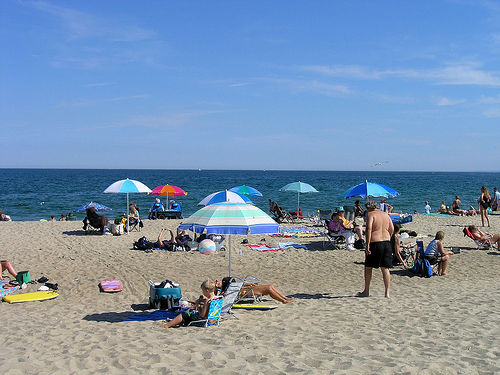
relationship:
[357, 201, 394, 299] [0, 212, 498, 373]
man on beach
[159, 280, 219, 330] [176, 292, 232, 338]
boy sitting in chair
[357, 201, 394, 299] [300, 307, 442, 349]
man walking on sand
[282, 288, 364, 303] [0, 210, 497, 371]
shadow on sand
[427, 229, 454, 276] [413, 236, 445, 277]
woman on chair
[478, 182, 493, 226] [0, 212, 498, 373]
woman on beach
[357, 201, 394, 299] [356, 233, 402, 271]
man wearing shorts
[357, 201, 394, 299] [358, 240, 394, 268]
man wearing shorts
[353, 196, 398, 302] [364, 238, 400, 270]
man wearing black shorts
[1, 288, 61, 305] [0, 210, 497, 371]
board on sand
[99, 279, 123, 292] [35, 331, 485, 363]
board on beach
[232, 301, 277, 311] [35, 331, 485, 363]
board on beach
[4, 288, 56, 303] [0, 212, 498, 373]
yellow boogieboard on beach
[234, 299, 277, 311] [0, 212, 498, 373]
yellow boogieboard on beach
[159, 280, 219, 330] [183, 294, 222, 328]
boy in chair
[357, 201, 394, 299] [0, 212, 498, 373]
man walking on beach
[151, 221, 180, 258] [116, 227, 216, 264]
person on towel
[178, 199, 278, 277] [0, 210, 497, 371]
umbrella in sand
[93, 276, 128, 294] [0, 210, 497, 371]
board laying sand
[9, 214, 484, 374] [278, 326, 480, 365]
shoreline covered sand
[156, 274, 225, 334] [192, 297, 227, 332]
boy sitting chair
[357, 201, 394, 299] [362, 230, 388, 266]
man wearing shorts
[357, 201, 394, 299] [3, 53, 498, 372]
man standing beach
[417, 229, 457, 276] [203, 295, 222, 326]
person sitting chair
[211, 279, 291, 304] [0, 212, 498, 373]
person laying down beach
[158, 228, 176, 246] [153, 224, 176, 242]
arms in the air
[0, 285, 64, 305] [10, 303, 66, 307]
board on the sand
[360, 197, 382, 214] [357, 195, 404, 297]
head of a man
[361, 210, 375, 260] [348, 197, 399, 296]
arm of a man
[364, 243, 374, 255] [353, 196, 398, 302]
hand of a man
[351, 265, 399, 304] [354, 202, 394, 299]
legs of a man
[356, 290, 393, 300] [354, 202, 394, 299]
feet of a man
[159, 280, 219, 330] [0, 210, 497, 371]
boy on the sand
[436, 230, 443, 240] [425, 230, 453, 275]
head of a woman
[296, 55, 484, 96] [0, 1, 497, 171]
clouds in the sky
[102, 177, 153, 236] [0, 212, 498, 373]
umbrella on the beach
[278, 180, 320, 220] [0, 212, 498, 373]
umbrella on the beach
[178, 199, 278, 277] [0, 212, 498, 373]
umbrella on the beach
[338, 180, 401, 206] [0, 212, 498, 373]
umbrella on the beach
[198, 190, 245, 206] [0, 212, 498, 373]
umbrella on the beach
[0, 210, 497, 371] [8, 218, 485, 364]
sand on the beach